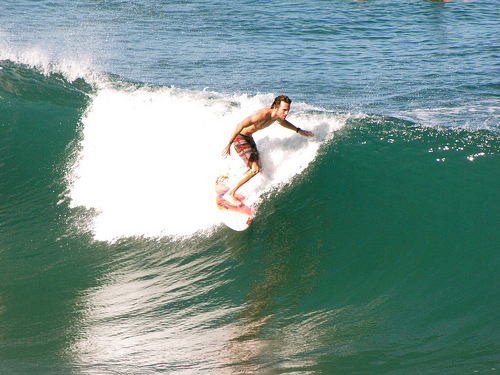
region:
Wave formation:
[3, 46, 208, 255]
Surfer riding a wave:
[205, 70, 330, 245]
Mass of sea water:
[85, 0, 490, 85]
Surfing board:
[199, 188, 258, 235]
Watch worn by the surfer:
[294, 121, 305, 139]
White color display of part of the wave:
[86, 83, 210, 233]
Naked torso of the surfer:
[234, 106, 275, 136]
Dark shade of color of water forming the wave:
[329, 154, 486, 321]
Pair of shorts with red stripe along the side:
[231, 136, 261, 168]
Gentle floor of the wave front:
[5, 296, 352, 373]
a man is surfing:
[116, 51, 435, 373]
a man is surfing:
[92, 67, 309, 284]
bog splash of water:
[35, 138, 199, 319]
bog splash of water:
[41, 91, 123, 283]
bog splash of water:
[14, 134, 221, 368]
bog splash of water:
[105, 242, 196, 359]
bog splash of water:
[78, 87, 180, 265]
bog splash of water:
[82, 112, 206, 300]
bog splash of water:
[67, 135, 218, 329]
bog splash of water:
[81, 178, 152, 303]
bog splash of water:
[135, 205, 242, 333]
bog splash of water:
[60, 142, 222, 364]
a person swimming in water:
[204, 75, 327, 252]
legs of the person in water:
[223, 155, 275, 211]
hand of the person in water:
[284, 117, 326, 142]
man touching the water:
[296, 116, 318, 147]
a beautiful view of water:
[69, 72, 399, 318]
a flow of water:
[94, 70, 438, 320]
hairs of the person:
[269, 95, 293, 105]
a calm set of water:
[36, 14, 496, 106]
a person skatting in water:
[228, 91, 330, 225]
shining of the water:
[99, 241, 224, 369]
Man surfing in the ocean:
[205, 86, 337, 238]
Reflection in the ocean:
[55, 242, 303, 370]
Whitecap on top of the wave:
[60, 69, 282, 249]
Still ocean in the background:
[327, 9, 497, 89]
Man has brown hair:
[267, 90, 296, 115]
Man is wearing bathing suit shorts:
[228, 126, 263, 175]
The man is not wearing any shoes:
[217, 167, 249, 217]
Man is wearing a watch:
[291, 124, 300, 139]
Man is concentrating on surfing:
[213, 82, 319, 264]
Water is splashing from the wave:
[40, 115, 131, 263]